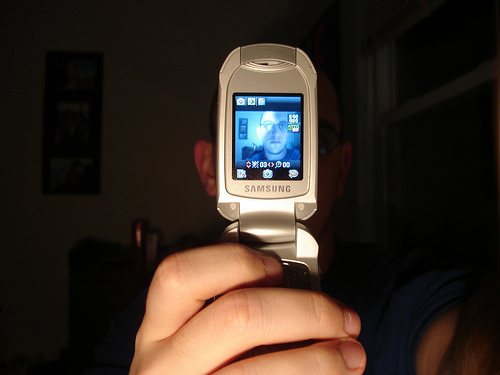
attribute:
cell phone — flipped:
[197, 38, 342, 308]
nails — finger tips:
[342, 304, 362, 339]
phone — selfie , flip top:
[195, 26, 364, 267]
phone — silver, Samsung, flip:
[215, 47, 342, 302]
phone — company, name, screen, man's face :
[213, 45, 322, 289]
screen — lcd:
[224, 89, 316, 181]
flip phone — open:
[211, 37, 326, 295]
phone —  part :
[208, 42, 323, 374]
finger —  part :
[168, 286, 362, 371]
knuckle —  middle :
[218, 288, 273, 333]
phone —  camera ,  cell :
[193, 34, 343, 271]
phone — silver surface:
[216, 37, 318, 300]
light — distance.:
[101, 199, 166, 301]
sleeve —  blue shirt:
[355, 275, 465, 371]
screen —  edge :
[232, 92, 302, 179]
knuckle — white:
[157, 253, 184, 289]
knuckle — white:
[223, 288, 265, 333]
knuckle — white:
[241, 355, 260, 373]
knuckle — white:
[134, 322, 155, 367]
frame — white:
[380, 41, 461, 158]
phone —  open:
[214, 34, 329, 284]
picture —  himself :
[183, 29, 336, 286]